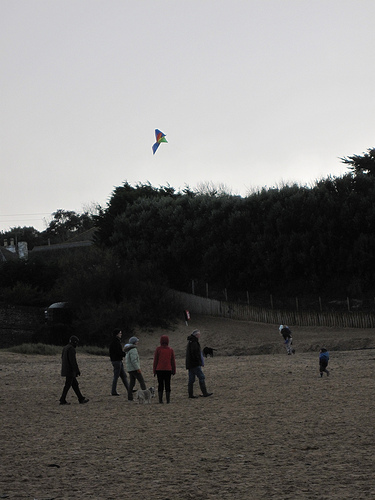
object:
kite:
[151, 127, 171, 156]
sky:
[0, 0, 375, 237]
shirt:
[152, 335, 176, 373]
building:
[43, 300, 68, 323]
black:
[188, 350, 194, 358]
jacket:
[318, 352, 330, 367]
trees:
[92, 148, 374, 295]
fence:
[166, 283, 374, 328]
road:
[188, 310, 373, 327]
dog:
[137, 386, 156, 405]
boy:
[317, 347, 329, 378]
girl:
[152, 334, 177, 404]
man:
[58, 335, 90, 405]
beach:
[0, 350, 375, 500]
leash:
[153, 375, 156, 388]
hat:
[191, 328, 201, 336]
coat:
[183, 335, 203, 370]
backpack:
[108, 339, 118, 362]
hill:
[0, 207, 178, 352]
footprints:
[194, 432, 203, 437]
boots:
[127, 392, 136, 403]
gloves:
[126, 353, 129, 357]